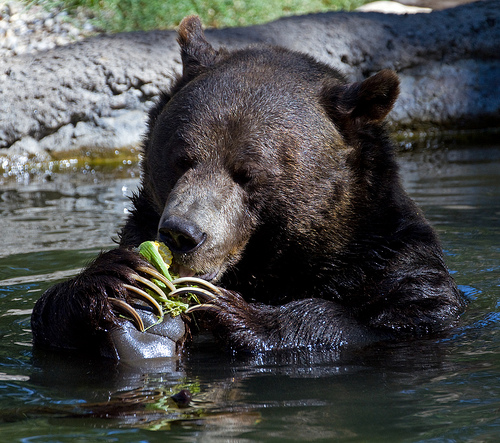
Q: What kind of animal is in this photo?
A: Bear.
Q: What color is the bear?
A: Dark brown.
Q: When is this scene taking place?
A: Day time.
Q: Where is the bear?
A: In the water.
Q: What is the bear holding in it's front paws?
A: It's foot.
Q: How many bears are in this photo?
A: One.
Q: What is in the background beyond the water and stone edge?
A: Grass.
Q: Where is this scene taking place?
A: Water.